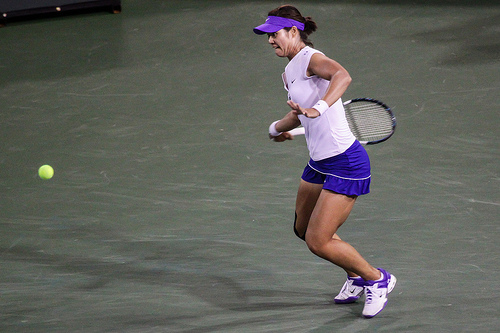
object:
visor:
[249, 16, 303, 35]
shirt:
[276, 46, 359, 165]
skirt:
[301, 139, 374, 195]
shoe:
[358, 269, 402, 318]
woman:
[252, 4, 397, 318]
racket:
[277, 94, 398, 146]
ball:
[35, 162, 57, 180]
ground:
[0, 0, 498, 333]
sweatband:
[312, 98, 330, 117]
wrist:
[317, 98, 337, 114]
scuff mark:
[128, 223, 261, 254]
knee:
[299, 227, 336, 255]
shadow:
[0, 226, 358, 308]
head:
[255, 3, 308, 59]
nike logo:
[287, 76, 299, 87]